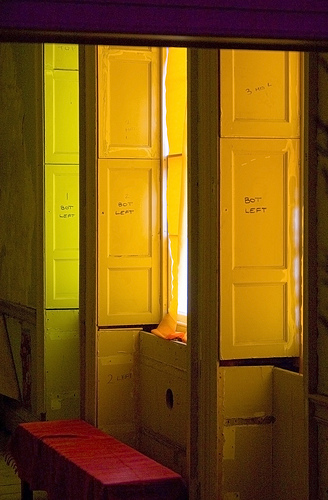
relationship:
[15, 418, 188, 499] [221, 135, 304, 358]
bench in front of door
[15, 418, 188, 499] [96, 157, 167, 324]
bench in front of door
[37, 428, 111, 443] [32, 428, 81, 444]
crease in cloth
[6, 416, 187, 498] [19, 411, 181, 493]
blanket draped over bench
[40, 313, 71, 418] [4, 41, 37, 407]
paint pilled from wall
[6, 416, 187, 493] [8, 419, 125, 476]
blanket on table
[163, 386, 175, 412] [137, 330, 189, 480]
hole in wood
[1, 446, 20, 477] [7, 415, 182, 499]
fringe on edge blanket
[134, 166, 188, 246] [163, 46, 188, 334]
light through window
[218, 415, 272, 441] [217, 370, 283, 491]
holes in board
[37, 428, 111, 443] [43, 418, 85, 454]
crease in blanket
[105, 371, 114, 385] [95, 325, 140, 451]
number 2 on wall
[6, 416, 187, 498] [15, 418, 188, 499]
blanket covers bench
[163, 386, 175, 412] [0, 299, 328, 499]
hole in wall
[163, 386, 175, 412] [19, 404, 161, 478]
hole near bench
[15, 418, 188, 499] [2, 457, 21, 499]
bench stands on floor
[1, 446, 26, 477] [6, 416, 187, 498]
fringe on blanket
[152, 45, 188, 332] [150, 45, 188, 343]
window with drapes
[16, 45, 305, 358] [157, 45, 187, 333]
drapes on window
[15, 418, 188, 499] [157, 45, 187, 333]
bench in front of window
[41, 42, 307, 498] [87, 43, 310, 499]
doors are different colors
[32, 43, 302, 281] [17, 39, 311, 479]
wall in room